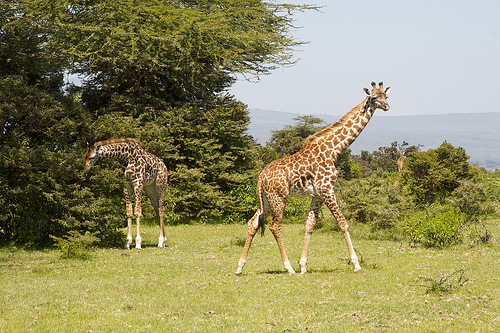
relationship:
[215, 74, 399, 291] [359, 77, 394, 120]
giraffe has head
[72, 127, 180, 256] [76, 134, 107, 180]
giraffe has head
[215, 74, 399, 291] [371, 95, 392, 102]
giraffe has eyes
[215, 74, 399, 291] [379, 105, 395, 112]
giraffe has mouth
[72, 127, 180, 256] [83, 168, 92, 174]
giraffe has mouth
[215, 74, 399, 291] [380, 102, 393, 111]
giraffe has nose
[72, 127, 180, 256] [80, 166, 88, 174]
giraffe has nose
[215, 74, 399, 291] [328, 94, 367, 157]
giraffe has neck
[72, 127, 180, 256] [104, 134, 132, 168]
giraffe has neck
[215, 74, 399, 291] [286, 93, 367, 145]
giraffe has mane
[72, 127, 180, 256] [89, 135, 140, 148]
giraffe has mane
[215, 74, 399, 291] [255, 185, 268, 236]
giraffe has tail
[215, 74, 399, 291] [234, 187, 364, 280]
giraffe has legs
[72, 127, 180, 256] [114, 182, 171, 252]
giraffe has legs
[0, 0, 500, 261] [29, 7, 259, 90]
bush has leaves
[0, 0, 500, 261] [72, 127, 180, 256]
bush behind giraffe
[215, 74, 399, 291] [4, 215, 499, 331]
giraffe in field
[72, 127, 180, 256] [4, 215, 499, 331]
giraffe in field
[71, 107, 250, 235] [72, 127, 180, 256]
bush near giraffe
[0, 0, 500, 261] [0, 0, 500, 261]
bush behind bush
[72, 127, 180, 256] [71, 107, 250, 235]
giraffe near bush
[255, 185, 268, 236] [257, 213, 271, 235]
tail has hair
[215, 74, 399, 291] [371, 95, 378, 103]
giraffe has eye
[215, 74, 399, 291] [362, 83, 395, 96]
giraffe has ears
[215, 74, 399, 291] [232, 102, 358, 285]
giraffe has body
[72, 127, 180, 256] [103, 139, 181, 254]
giraffe has body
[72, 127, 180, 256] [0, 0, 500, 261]
giraffe near bush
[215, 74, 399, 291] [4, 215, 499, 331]
giraffe in grass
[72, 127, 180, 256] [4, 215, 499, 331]
giraffe in grass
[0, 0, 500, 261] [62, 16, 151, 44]
bush has branch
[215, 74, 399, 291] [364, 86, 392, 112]
giraffe has face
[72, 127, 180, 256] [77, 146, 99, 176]
giraffe has face